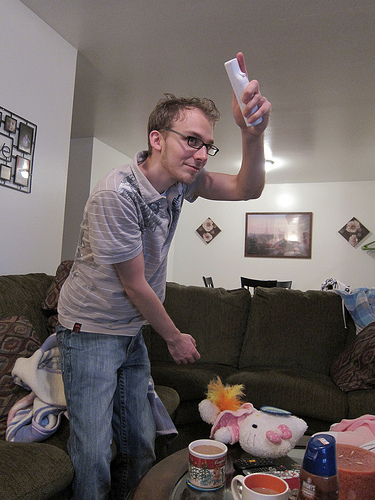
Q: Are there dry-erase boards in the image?
A: No, there are no dry-erase boards.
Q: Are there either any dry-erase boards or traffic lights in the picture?
A: No, there are no dry-erase boards or traffic lights.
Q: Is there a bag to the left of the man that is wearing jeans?
A: No, there is a picture to the left of the man.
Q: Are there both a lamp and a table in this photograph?
A: No, there is a table but no lamps.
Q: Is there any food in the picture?
A: No, there is no food.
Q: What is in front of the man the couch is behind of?
A: The table is in front of the man.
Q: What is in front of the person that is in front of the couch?
A: The table is in front of the man.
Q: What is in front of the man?
A: The table is in front of the man.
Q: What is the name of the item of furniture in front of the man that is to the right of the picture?
A: The piece of furniture is a table.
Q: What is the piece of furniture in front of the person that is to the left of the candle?
A: The piece of furniture is a table.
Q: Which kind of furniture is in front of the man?
A: The piece of furniture is a table.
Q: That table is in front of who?
A: The table is in front of the man.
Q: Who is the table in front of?
A: The table is in front of the man.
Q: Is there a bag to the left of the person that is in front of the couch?
A: No, there is a picture to the left of the man.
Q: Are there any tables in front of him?
A: Yes, there is a table in front of the man.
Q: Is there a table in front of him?
A: Yes, there is a table in front of the man.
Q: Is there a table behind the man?
A: No, the table is in front of the man.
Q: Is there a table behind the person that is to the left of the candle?
A: No, the table is in front of the man.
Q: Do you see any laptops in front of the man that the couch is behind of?
A: No, there is a table in front of the man.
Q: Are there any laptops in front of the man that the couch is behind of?
A: No, there is a table in front of the man.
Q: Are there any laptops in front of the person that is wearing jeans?
A: No, there is a table in front of the man.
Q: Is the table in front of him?
A: Yes, the table is in front of a man.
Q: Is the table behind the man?
A: No, the table is in front of the man.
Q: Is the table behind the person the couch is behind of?
A: No, the table is in front of the man.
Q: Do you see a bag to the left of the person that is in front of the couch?
A: No, there is a picture to the left of the man.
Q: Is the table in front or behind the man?
A: The table is in front of the man.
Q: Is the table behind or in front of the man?
A: The table is in front of the man.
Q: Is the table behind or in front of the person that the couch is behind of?
A: The table is in front of the man.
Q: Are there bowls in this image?
A: No, there are no bowls.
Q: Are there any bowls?
A: No, there are no bowls.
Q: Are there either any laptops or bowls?
A: No, there are no bowls or laptops.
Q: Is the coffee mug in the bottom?
A: Yes, the coffee mug is in the bottom of the image.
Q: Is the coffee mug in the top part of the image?
A: No, the coffee mug is in the bottom of the image.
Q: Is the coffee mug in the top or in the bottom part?
A: The coffee mug is in the bottom of the image.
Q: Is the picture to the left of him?
A: Yes, the picture is to the left of the man.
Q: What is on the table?
A: The coffee mug is on the table.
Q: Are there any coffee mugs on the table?
A: Yes, there is a coffee mug on the table.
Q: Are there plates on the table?
A: No, there is a coffee mug on the table.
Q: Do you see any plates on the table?
A: No, there is a coffee mug on the table.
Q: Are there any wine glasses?
A: No, there are no wine glasses.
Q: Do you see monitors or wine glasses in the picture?
A: No, there are no wine glasses or monitors.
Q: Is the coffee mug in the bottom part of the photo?
A: Yes, the coffee mug is in the bottom of the image.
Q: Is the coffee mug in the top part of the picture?
A: No, the coffee mug is in the bottom of the image.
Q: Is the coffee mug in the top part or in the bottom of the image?
A: The coffee mug is in the bottom of the image.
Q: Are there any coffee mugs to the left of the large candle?
A: Yes, there is a coffee mug to the left of the candle.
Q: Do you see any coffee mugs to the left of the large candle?
A: Yes, there is a coffee mug to the left of the candle.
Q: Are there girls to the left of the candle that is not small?
A: No, there is a coffee mug to the left of the candle.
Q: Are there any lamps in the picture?
A: No, there are no lamps.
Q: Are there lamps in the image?
A: No, there are no lamps.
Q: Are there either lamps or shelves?
A: No, there are no lamps or shelves.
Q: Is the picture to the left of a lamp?
A: No, the picture is to the left of the man.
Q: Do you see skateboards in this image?
A: No, there are no skateboards.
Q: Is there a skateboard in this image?
A: No, there are no skateboards.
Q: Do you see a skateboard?
A: No, there are no skateboards.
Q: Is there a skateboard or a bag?
A: No, there are no skateboards or bags.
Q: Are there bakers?
A: No, there are no bakers.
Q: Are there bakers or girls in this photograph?
A: No, there are no bakers or girls.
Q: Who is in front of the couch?
A: The man is in front of the couch.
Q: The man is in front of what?
A: The man is in front of the couch.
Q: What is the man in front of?
A: The man is in front of the couch.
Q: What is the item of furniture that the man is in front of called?
A: The piece of furniture is a couch.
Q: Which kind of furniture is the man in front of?
A: The man is in front of the couch.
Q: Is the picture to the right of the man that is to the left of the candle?
A: No, the picture is to the left of the man.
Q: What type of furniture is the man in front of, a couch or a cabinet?
A: The man is in front of a couch.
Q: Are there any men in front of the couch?
A: Yes, there is a man in front of the couch.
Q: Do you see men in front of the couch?
A: Yes, there is a man in front of the couch.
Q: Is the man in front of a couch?
A: Yes, the man is in front of a couch.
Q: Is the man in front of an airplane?
A: No, the man is in front of a couch.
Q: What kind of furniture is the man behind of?
A: The man is behind the table.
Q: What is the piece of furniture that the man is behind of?
A: The piece of furniture is a table.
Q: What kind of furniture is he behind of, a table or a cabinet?
A: The man is behind a table.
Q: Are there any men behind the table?
A: Yes, there is a man behind the table.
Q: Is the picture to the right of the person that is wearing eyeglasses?
A: No, the picture is to the left of the man.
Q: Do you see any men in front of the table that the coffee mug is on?
A: No, the man is behind the table.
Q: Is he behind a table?
A: Yes, the man is behind a table.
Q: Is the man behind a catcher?
A: No, the man is behind a table.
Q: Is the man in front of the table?
A: No, the man is behind the table.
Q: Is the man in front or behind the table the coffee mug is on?
A: The man is behind the table.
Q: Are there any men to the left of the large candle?
A: Yes, there is a man to the left of the candle.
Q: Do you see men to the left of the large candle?
A: Yes, there is a man to the left of the candle.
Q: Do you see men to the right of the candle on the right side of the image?
A: No, the man is to the left of the candle.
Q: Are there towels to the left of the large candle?
A: No, there is a man to the left of the candle.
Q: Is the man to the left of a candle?
A: Yes, the man is to the left of a candle.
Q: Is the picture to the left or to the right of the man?
A: The picture is to the left of the man.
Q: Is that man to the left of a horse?
A: No, the man is to the left of a candle.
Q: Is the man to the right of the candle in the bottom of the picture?
A: No, the man is to the left of the candle.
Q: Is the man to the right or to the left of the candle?
A: The man is to the left of the candle.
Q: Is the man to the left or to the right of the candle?
A: The man is to the left of the candle.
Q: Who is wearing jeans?
A: The man is wearing jeans.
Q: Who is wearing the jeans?
A: The man is wearing jeans.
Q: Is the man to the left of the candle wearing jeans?
A: Yes, the man is wearing jeans.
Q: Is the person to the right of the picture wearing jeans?
A: Yes, the man is wearing jeans.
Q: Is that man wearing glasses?
A: No, the man is wearing jeans.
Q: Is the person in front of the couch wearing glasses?
A: No, the man is wearing jeans.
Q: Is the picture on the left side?
A: Yes, the picture is on the left of the image.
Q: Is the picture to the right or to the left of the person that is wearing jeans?
A: The picture is to the left of the man.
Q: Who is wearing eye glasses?
A: The man is wearing eye glasses.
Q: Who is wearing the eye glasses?
A: The man is wearing eye glasses.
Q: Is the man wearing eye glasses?
A: Yes, the man is wearing eye glasses.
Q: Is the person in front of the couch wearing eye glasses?
A: Yes, the man is wearing eye glasses.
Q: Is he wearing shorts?
A: No, the man is wearing eye glasses.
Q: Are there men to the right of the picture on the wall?
A: Yes, there is a man to the right of the picture.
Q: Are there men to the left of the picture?
A: No, the man is to the right of the picture.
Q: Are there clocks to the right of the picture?
A: No, there is a man to the right of the picture.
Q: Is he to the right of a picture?
A: Yes, the man is to the right of a picture.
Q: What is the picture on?
A: The picture is on the wall.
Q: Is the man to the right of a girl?
A: No, the man is to the right of a picture.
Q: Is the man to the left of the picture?
A: No, the man is to the right of the picture.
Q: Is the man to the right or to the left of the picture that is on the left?
A: The man is to the right of the picture.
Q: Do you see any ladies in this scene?
A: No, there are no ladies.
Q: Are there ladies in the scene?
A: No, there are no ladies.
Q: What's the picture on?
A: The picture is on the wall.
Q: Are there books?
A: No, there are no books.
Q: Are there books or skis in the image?
A: No, there are no books or skis.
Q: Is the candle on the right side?
A: Yes, the candle is on the right of the image.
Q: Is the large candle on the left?
A: No, the candle is on the right of the image.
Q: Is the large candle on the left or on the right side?
A: The candle is on the right of the image.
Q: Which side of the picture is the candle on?
A: The candle is on the right of the image.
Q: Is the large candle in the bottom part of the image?
A: Yes, the candle is in the bottom of the image.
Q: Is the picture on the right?
A: No, the picture is on the left of the image.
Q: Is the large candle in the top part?
A: No, the candle is in the bottom of the image.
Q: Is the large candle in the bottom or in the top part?
A: The candle is in the bottom of the image.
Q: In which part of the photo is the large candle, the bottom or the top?
A: The candle is in the bottom of the image.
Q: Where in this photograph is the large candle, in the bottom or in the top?
A: The candle is in the bottom of the image.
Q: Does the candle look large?
A: Yes, the candle is large.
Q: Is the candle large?
A: Yes, the candle is large.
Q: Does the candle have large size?
A: Yes, the candle is large.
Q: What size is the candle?
A: The candle is large.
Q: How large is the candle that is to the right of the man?
A: The candle is large.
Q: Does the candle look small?
A: No, the candle is large.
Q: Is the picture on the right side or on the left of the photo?
A: The picture is on the left of the image.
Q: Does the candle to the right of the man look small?
A: No, the candle is large.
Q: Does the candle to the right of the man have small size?
A: No, the candle is large.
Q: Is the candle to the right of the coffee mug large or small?
A: The candle is large.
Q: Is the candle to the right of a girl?
A: No, the candle is to the right of the coffee mug.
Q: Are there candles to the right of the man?
A: Yes, there is a candle to the right of the man.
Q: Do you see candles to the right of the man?
A: Yes, there is a candle to the right of the man.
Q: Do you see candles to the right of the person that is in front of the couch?
A: Yes, there is a candle to the right of the man.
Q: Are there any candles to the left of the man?
A: No, the candle is to the right of the man.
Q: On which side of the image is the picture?
A: The picture is on the left of the image.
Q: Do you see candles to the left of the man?
A: No, the candle is to the right of the man.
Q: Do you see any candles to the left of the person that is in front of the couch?
A: No, the candle is to the right of the man.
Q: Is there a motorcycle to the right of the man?
A: No, there is a candle to the right of the man.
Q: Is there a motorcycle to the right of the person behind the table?
A: No, there is a candle to the right of the man.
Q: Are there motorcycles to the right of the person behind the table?
A: No, there is a candle to the right of the man.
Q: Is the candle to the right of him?
A: Yes, the candle is to the right of a man.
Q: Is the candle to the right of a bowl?
A: No, the candle is to the right of a man.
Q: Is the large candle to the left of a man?
A: No, the candle is to the right of a man.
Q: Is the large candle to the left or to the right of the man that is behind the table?
A: The candle is to the right of the man.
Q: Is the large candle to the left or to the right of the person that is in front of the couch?
A: The candle is to the right of the man.